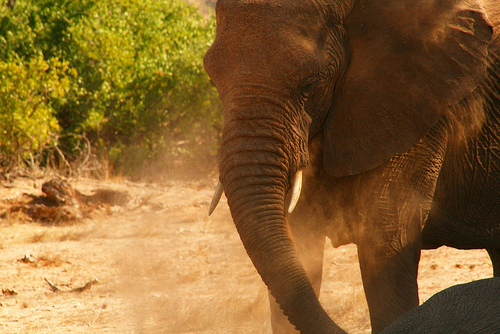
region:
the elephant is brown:
[188, 74, 493, 272]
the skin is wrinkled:
[380, 160, 480, 210]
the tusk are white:
[199, 141, 349, 232]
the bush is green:
[54, 65, 185, 121]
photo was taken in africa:
[1, 40, 491, 327]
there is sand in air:
[132, 136, 215, 211]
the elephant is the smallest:
[406, 269, 496, 326]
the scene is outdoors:
[4, 57, 496, 328]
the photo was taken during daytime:
[4, 55, 493, 332]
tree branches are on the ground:
[31, 145, 136, 225]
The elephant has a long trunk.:
[220, 167, 357, 331]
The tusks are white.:
[203, 169, 319, 218]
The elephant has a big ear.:
[354, 16, 497, 155]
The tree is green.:
[3, 18, 195, 123]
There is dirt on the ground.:
[43, 251, 191, 332]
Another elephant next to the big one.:
[393, 285, 497, 332]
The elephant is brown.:
[199, 0, 476, 260]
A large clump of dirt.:
[17, 171, 143, 234]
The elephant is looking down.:
[166, 47, 346, 162]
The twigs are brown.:
[43, 136, 124, 182]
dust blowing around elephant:
[47, 30, 475, 295]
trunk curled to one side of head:
[190, 121, 367, 328]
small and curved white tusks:
[190, 155, 306, 225]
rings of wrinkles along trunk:
[220, 100, 291, 225]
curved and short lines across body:
[441, 127, 491, 212]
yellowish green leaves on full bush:
[7, 5, 203, 170]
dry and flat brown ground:
[26, 175, 211, 317]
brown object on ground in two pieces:
[15, 165, 125, 240]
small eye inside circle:
[281, 60, 321, 110]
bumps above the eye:
[187, 35, 332, 91]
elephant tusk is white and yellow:
[282, 135, 318, 234]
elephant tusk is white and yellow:
[189, 152, 247, 224]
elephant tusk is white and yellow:
[263, 161, 314, 223]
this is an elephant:
[223, 8, 494, 273]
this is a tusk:
[288, 173, 299, 218]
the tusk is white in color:
[291, 180, 297, 195]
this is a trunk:
[249, 202, 289, 278]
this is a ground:
[71, 242, 148, 320]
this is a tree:
[64, 25, 166, 132]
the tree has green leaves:
[86, 31, 133, 90]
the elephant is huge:
[224, 8, 498, 253]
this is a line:
[223, 128, 262, 139]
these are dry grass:
[131, 258, 217, 331]